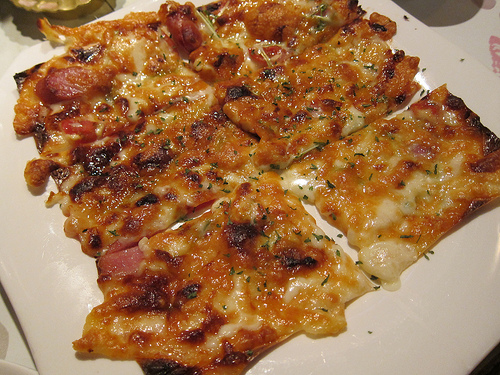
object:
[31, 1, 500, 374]
cheese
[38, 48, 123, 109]
ham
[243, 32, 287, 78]
sausage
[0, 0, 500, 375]
crust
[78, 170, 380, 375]
slice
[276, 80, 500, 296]
slice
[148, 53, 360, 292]
parsley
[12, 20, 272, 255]
piece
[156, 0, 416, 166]
piece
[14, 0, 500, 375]
top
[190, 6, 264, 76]
garlic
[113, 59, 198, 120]
oil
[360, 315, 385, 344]
speck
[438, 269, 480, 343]
surface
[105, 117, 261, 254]
space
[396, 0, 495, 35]
shadow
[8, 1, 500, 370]
photo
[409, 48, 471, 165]
corner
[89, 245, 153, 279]
ham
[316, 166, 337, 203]
herbs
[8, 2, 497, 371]
table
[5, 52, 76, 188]
border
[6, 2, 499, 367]
pizza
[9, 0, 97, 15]
cotainer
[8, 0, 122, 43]
shadow